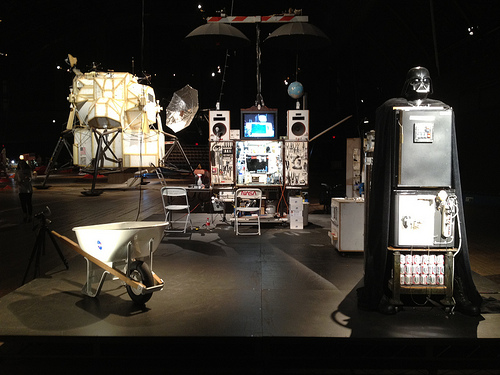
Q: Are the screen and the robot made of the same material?
A: Yes, both the screen and the robot are made of metal.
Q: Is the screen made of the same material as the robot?
A: Yes, both the screen and the robot are made of metal.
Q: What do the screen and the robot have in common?
A: The material, both the screen and the robot are metallic.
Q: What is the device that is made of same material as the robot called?
A: The device is a screen.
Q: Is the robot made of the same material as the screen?
A: Yes, both the robot and the screen are made of metal.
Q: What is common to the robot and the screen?
A: The material, both the robot and the screen are metallic.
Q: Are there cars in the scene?
A: No, there are no cars.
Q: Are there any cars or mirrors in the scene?
A: No, there are no cars or mirrors.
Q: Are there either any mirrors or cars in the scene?
A: No, there are no cars or mirrors.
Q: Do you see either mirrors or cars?
A: No, there are no cars or mirrors.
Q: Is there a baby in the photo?
A: No, there are no babies.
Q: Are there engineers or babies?
A: No, there are no babies or engineers.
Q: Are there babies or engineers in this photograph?
A: No, there are no babies or engineers.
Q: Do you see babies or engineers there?
A: No, there are no babies or engineers.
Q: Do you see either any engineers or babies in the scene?
A: No, there are no babies or engineers.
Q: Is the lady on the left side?
A: Yes, the lady is on the left of the image.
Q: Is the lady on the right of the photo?
A: No, the lady is on the left of the image.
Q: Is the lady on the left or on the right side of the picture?
A: The lady is on the left of the image.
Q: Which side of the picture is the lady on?
A: The lady is on the left of the image.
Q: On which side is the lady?
A: The lady is on the left of the image.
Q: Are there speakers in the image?
A: Yes, there is a speaker.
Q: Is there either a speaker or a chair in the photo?
A: Yes, there is a speaker.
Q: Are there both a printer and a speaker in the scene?
A: No, there is a speaker but no printers.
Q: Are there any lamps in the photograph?
A: No, there are no lamps.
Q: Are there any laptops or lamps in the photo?
A: No, there are no lamps or laptops.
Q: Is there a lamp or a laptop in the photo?
A: No, there are no lamps or laptops.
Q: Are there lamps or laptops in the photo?
A: No, there are no lamps or laptops.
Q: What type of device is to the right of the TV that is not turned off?
A: The device is a speaker.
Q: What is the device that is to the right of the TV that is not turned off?
A: The device is a speaker.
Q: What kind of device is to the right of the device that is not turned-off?
A: The device is a speaker.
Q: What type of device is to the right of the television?
A: The device is a speaker.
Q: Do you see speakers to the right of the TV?
A: Yes, there is a speaker to the right of the TV.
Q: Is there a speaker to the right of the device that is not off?
A: Yes, there is a speaker to the right of the TV.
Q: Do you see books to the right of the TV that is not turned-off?
A: No, there is a speaker to the right of the TV.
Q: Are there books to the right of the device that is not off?
A: No, there is a speaker to the right of the TV.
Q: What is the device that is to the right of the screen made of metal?
A: The device is a speaker.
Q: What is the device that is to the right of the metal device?
A: The device is a speaker.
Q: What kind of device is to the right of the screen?
A: The device is a speaker.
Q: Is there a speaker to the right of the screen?
A: Yes, there is a speaker to the right of the screen.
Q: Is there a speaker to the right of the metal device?
A: Yes, there is a speaker to the right of the screen.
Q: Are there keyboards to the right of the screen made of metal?
A: No, there is a speaker to the right of the screen.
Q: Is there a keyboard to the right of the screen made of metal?
A: No, there is a speaker to the right of the screen.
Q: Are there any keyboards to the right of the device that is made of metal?
A: No, there is a speaker to the right of the screen.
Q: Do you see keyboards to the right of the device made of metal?
A: No, there is a speaker to the right of the screen.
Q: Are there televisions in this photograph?
A: Yes, there is a television.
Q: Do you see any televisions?
A: Yes, there is a television.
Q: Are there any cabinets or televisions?
A: Yes, there is a television.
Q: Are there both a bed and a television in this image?
A: No, there is a television but no beds.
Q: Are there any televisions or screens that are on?
A: Yes, the television is on.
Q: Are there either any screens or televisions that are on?
A: Yes, the television is on.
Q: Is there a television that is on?
A: Yes, there is a television that is on.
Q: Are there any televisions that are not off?
A: Yes, there is a television that is on.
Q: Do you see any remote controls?
A: No, there are no remote controls.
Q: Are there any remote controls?
A: No, there are no remote controls.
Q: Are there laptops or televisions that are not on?
A: No, there is a television but it is on.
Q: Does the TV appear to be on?
A: Yes, the TV is on.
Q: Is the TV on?
A: Yes, the TV is on.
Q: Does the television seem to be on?
A: Yes, the television is on.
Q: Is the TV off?
A: No, the TV is on.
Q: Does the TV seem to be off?
A: No, the TV is on.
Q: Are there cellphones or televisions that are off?
A: No, there is a television but it is on.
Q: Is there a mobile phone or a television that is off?
A: No, there is a television but it is on.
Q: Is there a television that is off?
A: No, there is a television but it is on.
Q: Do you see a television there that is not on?
A: No, there is a television but it is on.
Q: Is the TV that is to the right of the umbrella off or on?
A: The TV is on.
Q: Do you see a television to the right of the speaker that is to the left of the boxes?
A: No, the television is to the left of the speaker.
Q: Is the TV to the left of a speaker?
A: Yes, the TV is to the left of a speaker.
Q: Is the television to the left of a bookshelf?
A: No, the television is to the left of a speaker.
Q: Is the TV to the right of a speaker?
A: No, the TV is to the left of a speaker.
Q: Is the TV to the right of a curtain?
A: No, the TV is to the right of the umbrella.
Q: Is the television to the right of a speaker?
A: Yes, the television is to the right of a speaker.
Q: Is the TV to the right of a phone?
A: No, the TV is to the right of a speaker.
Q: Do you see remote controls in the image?
A: No, there are no remote controls.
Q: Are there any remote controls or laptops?
A: No, there are no remote controls or laptops.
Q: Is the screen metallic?
A: Yes, the screen is metallic.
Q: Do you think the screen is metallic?
A: Yes, the screen is metallic.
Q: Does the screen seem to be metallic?
A: Yes, the screen is metallic.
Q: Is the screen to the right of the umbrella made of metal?
A: Yes, the screen is made of metal.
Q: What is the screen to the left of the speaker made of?
A: The screen is made of metal.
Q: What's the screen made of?
A: The screen is made of metal.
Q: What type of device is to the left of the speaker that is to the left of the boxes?
A: The device is a screen.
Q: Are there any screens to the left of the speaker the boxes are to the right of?
A: Yes, there is a screen to the left of the speaker.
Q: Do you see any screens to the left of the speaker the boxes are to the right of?
A: Yes, there is a screen to the left of the speaker.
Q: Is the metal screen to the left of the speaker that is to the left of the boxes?
A: Yes, the screen is to the left of the speaker.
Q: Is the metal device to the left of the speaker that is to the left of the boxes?
A: Yes, the screen is to the left of the speaker.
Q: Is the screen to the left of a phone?
A: No, the screen is to the left of the speaker.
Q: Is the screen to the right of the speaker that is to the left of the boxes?
A: No, the screen is to the left of the speaker.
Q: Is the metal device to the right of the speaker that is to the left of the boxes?
A: No, the screen is to the left of the speaker.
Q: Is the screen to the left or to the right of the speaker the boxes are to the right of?
A: The screen is to the left of the speaker.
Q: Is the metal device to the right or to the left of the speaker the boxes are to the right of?
A: The screen is to the left of the speaker.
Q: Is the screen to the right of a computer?
A: No, the screen is to the right of the speaker.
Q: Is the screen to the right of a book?
A: No, the screen is to the right of the umbrella.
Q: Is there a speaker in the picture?
A: Yes, there is a speaker.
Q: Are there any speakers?
A: Yes, there is a speaker.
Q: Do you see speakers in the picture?
A: Yes, there is a speaker.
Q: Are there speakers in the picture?
A: Yes, there is a speaker.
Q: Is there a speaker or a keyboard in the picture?
A: Yes, there is a speaker.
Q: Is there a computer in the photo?
A: No, there are no computers.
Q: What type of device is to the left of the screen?
A: The device is a speaker.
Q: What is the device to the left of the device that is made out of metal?
A: The device is a speaker.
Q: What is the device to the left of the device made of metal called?
A: The device is a speaker.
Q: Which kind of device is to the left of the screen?
A: The device is a speaker.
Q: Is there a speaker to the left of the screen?
A: Yes, there is a speaker to the left of the screen.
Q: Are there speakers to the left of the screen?
A: Yes, there is a speaker to the left of the screen.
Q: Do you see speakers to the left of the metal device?
A: Yes, there is a speaker to the left of the screen.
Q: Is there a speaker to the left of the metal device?
A: Yes, there is a speaker to the left of the screen.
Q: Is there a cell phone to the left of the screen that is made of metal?
A: No, there is a speaker to the left of the screen.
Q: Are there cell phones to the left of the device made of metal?
A: No, there is a speaker to the left of the screen.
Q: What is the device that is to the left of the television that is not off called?
A: The device is a speaker.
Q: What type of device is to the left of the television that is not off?
A: The device is a speaker.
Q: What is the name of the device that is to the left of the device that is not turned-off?
A: The device is a speaker.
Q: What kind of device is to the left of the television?
A: The device is a speaker.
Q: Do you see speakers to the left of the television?
A: Yes, there is a speaker to the left of the television.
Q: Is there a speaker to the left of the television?
A: Yes, there is a speaker to the left of the television.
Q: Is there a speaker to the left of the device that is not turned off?
A: Yes, there is a speaker to the left of the television.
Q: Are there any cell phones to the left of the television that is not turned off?
A: No, there is a speaker to the left of the TV.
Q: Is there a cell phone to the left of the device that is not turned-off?
A: No, there is a speaker to the left of the TV.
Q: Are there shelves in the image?
A: No, there are no shelves.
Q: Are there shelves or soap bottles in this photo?
A: No, there are no shelves or soap bottles.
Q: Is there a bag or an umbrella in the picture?
A: Yes, there is an umbrella.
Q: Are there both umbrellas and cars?
A: No, there is an umbrella but no cars.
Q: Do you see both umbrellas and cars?
A: No, there is an umbrella but no cars.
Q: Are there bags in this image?
A: No, there are no bags.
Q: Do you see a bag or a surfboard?
A: No, there are no bags or surfboards.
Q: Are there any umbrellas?
A: Yes, there is an umbrella.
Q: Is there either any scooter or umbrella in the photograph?
A: Yes, there is an umbrella.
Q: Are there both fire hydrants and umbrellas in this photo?
A: No, there is an umbrella but no fire hydrants.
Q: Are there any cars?
A: No, there are no cars.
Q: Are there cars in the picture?
A: No, there are no cars.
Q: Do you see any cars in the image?
A: No, there are no cars.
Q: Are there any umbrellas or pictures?
A: Yes, there is an umbrella.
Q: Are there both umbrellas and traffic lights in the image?
A: No, there is an umbrella but no traffic lights.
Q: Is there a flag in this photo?
A: No, there are no flags.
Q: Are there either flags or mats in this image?
A: No, there are no flags or mats.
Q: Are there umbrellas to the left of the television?
A: Yes, there is an umbrella to the left of the television.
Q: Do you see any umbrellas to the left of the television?
A: Yes, there is an umbrella to the left of the television.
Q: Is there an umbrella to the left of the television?
A: Yes, there is an umbrella to the left of the television.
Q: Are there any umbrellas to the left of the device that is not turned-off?
A: Yes, there is an umbrella to the left of the television.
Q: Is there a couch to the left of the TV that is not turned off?
A: No, there is an umbrella to the left of the TV.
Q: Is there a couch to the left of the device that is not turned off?
A: No, there is an umbrella to the left of the TV.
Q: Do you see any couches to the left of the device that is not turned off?
A: No, there is an umbrella to the left of the TV.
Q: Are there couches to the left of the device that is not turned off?
A: No, there is an umbrella to the left of the TV.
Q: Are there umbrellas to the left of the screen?
A: Yes, there is an umbrella to the left of the screen.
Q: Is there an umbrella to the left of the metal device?
A: Yes, there is an umbrella to the left of the screen.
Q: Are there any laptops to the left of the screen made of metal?
A: No, there is an umbrella to the left of the screen.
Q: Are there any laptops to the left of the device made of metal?
A: No, there is an umbrella to the left of the screen.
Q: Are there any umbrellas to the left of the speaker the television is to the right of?
A: Yes, there is an umbrella to the left of the speaker.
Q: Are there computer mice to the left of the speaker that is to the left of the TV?
A: No, there is an umbrella to the left of the speaker.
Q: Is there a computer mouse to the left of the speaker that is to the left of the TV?
A: No, there is an umbrella to the left of the speaker.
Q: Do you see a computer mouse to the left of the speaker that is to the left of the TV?
A: No, there is an umbrella to the left of the speaker.